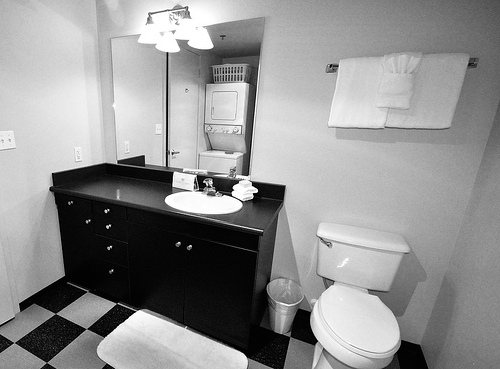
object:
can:
[261, 274, 304, 335]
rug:
[95, 306, 248, 367]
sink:
[166, 189, 243, 220]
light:
[187, 22, 215, 54]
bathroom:
[0, 0, 499, 368]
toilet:
[311, 218, 414, 366]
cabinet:
[132, 227, 256, 352]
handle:
[185, 244, 195, 256]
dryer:
[202, 83, 249, 134]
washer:
[198, 149, 243, 179]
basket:
[208, 58, 253, 83]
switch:
[0, 130, 16, 152]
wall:
[3, 1, 105, 307]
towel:
[326, 53, 397, 137]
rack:
[326, 53, 480, 73]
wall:
[98, 1, 499, 347]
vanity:
[49, 159, 285, 351]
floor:
[59, 292, 120, 331]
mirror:
[108, 14, 268, 178]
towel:
[385, 49, 469, 131]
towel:
[377, 49, 422, 115]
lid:
[319, 283, 400, 355]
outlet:
[73, 146, 85, 166]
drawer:
[90, 200, 125, 220]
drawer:
[92, 217, 130, 242]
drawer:
[94, 229, 130, 261]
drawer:
[94, 256, 131, 304]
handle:
[325, 240, 333, 250]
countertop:
[65, 171, 284, 232]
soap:
[238, 177, 252, 188]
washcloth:
[231, 183, 258, 195]